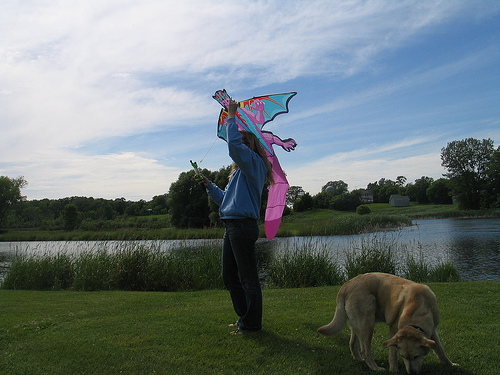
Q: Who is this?
A: Person.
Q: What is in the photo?
A: Dog.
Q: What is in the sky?
A: Clouds.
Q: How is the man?
A: Standing.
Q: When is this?
A: Daytime.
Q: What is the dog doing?
A: Sniffing.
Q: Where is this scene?
A: In a park.